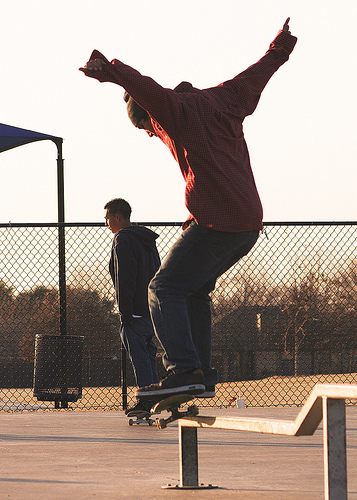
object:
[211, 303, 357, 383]
building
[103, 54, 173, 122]
arm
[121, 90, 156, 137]
head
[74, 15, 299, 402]
guy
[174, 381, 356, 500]
rail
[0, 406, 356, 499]
area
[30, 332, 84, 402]
bin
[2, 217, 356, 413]
fence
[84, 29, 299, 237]
jacket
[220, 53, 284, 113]
arm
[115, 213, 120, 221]
ear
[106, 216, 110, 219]
eye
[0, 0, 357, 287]
sky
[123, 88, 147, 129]
cap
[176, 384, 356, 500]
ramp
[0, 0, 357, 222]
cloudless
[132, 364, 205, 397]
foot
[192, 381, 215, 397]
foot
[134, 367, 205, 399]
feet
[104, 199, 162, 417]
person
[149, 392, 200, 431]
skateboard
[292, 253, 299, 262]
hole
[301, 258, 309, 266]
hole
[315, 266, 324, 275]
hole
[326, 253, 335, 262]
hole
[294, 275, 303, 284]
hole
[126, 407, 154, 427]
skateboard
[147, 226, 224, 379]
leg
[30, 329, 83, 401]
holes